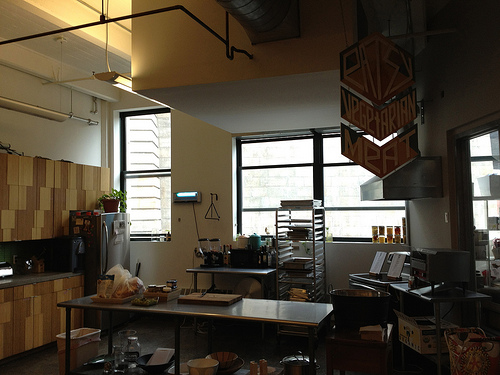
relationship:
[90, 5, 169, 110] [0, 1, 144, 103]
light on ceiling